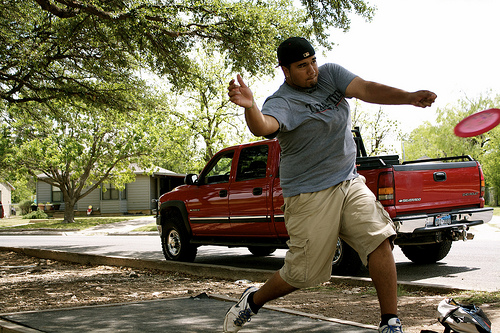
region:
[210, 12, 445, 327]
Man trowing a fresbee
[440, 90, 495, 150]
Frisbee flies in the air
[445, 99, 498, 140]
Frisbee is red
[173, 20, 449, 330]
Man has a cap on his head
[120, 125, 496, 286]
Red truck park on side of road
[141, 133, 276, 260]
Two double door of truck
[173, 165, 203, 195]
Mirror of driver side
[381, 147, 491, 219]
Back door of truck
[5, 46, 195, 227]
Tree on the street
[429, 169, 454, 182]
Handle back door of red car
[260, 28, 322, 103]
The man is wearing a hat.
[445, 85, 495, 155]
A red frisbee.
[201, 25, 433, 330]
The man is playing frisbee.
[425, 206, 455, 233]
A license plate.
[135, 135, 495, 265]
A red pickup truck.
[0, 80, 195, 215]
A large tree is in front of the house.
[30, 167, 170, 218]
A grey house.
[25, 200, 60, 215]
A row of planters.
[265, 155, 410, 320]
The man is wearing cargo shorts.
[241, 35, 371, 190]
The man is wearing a gray shirt.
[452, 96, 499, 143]
the frisbee is red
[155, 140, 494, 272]
the pickup truck is red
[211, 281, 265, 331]
the sneaker is white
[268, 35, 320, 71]
the ball cap is black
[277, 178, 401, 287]
the shorts are beige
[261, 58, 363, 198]
the tee shirt is grey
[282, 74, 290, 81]
the man wears an earring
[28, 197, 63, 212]
there are flower pots in front of the house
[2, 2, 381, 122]
the leaves are green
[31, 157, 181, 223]
the house is grey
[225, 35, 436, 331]
man in grey shirt playing frisbee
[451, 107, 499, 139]
red frisbee thrown by a man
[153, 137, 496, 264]
red pickup truck on road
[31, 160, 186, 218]
green house amongst trees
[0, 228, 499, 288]
road under red truck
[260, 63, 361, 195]
grey shirt on frisbee throwing man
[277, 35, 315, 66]
black cap on frisbee throwing man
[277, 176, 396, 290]
beige shorts on frisbee throwing man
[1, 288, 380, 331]
sidewalk under frisbee throwing man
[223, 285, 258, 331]
white tennis shoe worn by frisbee throwing man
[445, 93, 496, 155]
Red frizbee flying thru air.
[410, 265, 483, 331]
Back pack on the ground.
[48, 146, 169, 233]
Green and white house.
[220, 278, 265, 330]
A white and black shoe.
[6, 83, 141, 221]
Green trees with brown trunks.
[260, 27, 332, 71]
Dark colored baseball hat.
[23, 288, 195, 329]
Part of a sidewalk.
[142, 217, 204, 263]
Black tire with silver rim.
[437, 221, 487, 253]
Silver tail hitch on truck.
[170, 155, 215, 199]
Side mirror on a vehicle.